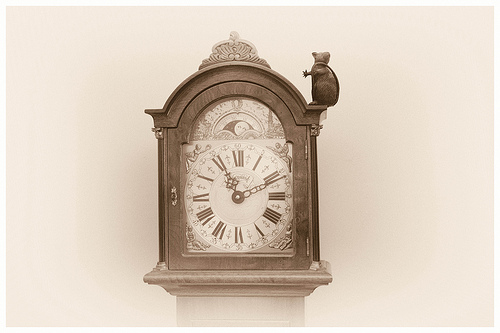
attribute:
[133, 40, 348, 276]
grandfather clock — old fashioned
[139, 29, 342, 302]
clock — old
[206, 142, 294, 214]
11:11 — time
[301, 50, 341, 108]
mouse — little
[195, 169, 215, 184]
numeral — roman, ten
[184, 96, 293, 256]
analogue clock — analog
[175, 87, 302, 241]
clock — old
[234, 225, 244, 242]
vi — upside down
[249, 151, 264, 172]
number — one, roman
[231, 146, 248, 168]
roman numeral — twelve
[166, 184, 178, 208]
knob — little, gold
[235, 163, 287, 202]
hand — longer, decorative